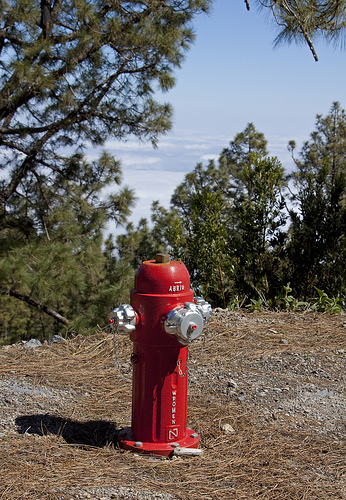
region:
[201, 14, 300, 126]
The sky is clear and blue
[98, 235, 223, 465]
The fire hydrant on the ground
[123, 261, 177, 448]
The fire hydrant is red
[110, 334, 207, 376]
The chains on the hydrant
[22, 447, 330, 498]
The twigs on the ground are brown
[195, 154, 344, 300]
The trees are very healthy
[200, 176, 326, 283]
The leaves of the tree are green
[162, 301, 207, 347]
The faucet cover is silver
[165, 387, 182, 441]
The logo on the fire hydrant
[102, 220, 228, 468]
the hydrant is red and silver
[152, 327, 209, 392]
a chain on the hydrant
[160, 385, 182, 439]
letters are on the hydrant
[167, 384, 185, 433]
the letters are white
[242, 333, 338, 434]
the gravel is grey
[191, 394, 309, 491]
the pine needles are brown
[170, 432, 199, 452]
bolts in the bottom of the hydrant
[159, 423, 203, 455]
the bolts are grey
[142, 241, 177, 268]
the top of the hydrant has a brown bolt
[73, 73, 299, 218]
the sky is partly cloudy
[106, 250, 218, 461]
a red fire hydrant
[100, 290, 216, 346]
metal caps on a fire hydrant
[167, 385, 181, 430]
words on a fire hydrant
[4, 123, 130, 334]
pine trees in the distance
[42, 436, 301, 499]
pine needles on the ground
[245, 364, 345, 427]
rocks on the ground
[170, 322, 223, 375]
a chain on a fire hydrant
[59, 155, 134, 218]
branches on a tree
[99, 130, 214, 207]
clouds beyond the trees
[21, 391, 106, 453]
shadow on the ground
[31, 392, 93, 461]
shadow of the hydrant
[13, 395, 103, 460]
shadow of the object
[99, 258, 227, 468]
a hydrant in ground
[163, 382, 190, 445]
a white text in object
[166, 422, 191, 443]
a small symbol in machine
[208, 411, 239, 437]
a white particle in ground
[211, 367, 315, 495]
sun rays on the ground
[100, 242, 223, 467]
A red water hydrant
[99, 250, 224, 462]
A red water hydrant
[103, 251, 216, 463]
A red water hydrant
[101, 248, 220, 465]
A red water hydrant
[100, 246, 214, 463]
A red water hydrant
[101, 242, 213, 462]
red fire hydrant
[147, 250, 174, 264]
brown knob on fire hydrant top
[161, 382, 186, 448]
white words written on fire hydrant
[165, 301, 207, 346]
silver knob on fire hydrant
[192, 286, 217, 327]
silver knob on fire hydrant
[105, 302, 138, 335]
silver knob on fire hydrant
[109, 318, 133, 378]
silver metal chain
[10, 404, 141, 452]
black shadow of fire hydrant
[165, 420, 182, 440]
white 2 on fire hydrant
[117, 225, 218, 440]
red and gray fire hydrant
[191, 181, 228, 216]
green leaves on brown tree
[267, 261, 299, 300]
green leaves on brown tree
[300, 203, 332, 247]
green leaves on brown tree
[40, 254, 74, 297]
green leaves on brown tree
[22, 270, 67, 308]
green leaves on brown tree